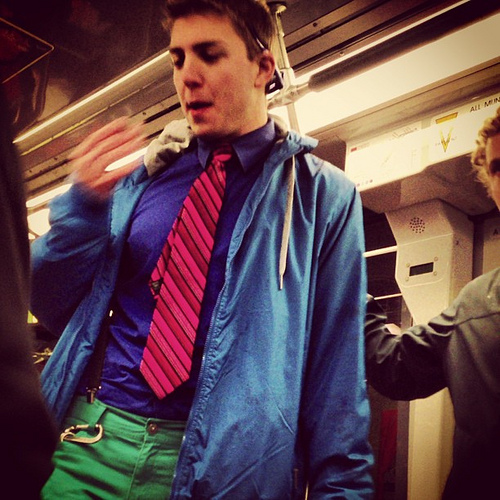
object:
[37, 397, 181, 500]
pants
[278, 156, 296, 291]
lace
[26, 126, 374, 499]
jacket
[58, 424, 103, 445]
carabiner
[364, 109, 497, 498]
man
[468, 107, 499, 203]
hair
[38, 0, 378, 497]
man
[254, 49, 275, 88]
ear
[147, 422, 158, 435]
button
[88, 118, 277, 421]
shirt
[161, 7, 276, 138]
head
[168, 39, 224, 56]
eyebrows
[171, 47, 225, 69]
eyes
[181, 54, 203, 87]
nose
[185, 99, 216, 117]
mouth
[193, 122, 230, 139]
chin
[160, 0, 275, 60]
hair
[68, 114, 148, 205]
hand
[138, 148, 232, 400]
red tie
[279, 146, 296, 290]
string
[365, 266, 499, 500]
jacket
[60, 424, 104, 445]
clip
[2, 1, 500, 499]
subway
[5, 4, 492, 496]
bars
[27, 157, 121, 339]
arm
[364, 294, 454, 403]
arm